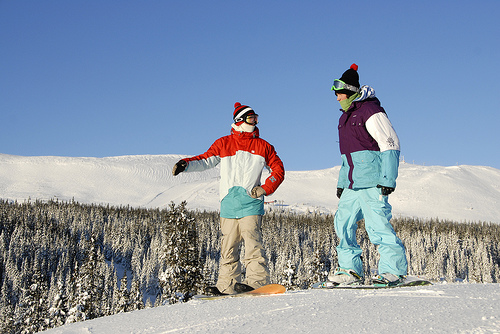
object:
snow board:
[191, 282, 286, 297]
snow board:
[308, 275, 433, 287]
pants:
[333, 187, 407, 277]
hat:
[335, 62, 361, 98]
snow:
[130, 240, 151, 255]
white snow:
[83, 283, 320, 332]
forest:
[0, 196, 497, 334]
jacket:
[337, 97, 399, 190]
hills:
[0, 154, 500, 227]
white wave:
[153, 156, 499, 199]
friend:
[172, 101, 286, 295]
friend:
[328, 62, 408, 284]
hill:
[31, 282, 500, 334]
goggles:
[235, 113, 259, 126]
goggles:
[331, 79, 360, 92]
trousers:
[215, 215, 270, 294]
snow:
[368, 282, 462, 310]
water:
[104, 220, 147, 316]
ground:
[80, 169, 149, 177]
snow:
[41, 158, 186, 196]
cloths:
[181, 121, 285, 219]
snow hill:
[0, 153, 499, 334]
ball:
[114, 148, 207, 197]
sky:
[0, 0, 499, 171]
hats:
[233, 102, 255, 124]